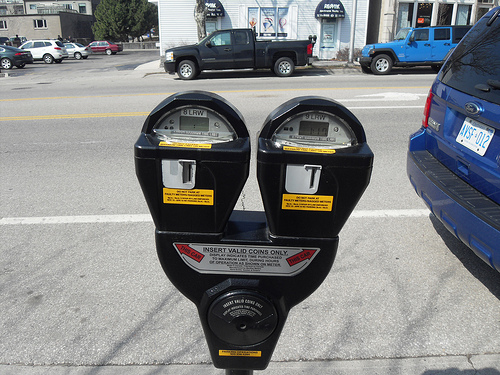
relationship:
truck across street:
[161, 26, 314, 77] [4, 77, 493, 359]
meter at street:
[131, 88, 378, 374] [4, 77, 493, 359]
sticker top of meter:
[160, 139, 213, 151] [131, 88, 378, 374]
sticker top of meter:
[283, 144, 337, 156] [131, 88, 378, 374]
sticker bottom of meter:
[161, 188, 215, 207] [131, 88, 378, 374]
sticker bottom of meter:
[279, 193, 335, 213] [131, 88, 378, 374]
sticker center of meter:
[174, 238, 320, 278] [131, 88, 378, 374]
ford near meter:
[403, 2, 495, 279] [131, 88, 378, 374]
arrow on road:
[337, 88, 429, 104] [4, 77, 493, 359]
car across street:
[360, 25, 469, 74] [4, 77, 493, 359]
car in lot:
[0, 46, 32, 72] [1, 41, 162, 76]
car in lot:
[88, 38, 121, 56] [1, 41, 162, 76]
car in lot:
[18, 38, 70, 65] [1, 41, 162, 76]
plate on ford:
[458, 117, 495, 156] [403, 2, 495, 279]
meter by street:
[131, 88, 378, 374] [4, 77, 493, 359]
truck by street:
[161, 26, 314, 77] [4, 77, 493, 359]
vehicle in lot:
[0, 46, 32, 72] [1, 41, 162, 76]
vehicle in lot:
[18, 38, 70, 65] [1, 41, 162, 76]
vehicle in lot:
[62, 41, 89, 62] [1, 41, 162, 76]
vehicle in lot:
[88, 38, 121, 56] [1, 41, 162, 76]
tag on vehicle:
[458, 117, 495, 156] [403, 2, 495, 279]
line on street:
[1, 109, 152, 123] [4, 77, 493, 359]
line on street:
[2, 206, 430, 228] [4, 77, 493, 359]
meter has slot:
[131, 88, 378, 374] [178, 159, 194, 186]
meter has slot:
[131, 88, 378, 374] [306, 166, 318, 191]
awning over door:
[201, 0, 226, 19] [203, 18, 223, 45]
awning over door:
[315, 0, 345, 22] [318, 20, 339, 59]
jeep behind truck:
[360, 25, 469, 74] [161, 26, 314, 77]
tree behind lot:
[93, 0, 159, 43] [1, 41, 162, 76]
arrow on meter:
[174, 240, 205, 266] [131, 88, 378, 374]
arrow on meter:
[286, 246, 316, 267] [131, 88, 378, 374]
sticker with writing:
[161, 188, 215, 207] [164, 193, 213, 200]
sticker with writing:
[279, 193, 335, 213] [284, 198, 332, 206]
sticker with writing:
[279, 193, 335, 213] [164, 193, 213, 200]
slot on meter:
[178, 159, 194, 186] [131, 88, 378, 374]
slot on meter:
[306, 166, 318, 191] [131, 88, 378, 374]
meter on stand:
[134, 88, 252, 238] [154, 235, 341, 371]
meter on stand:
[255, 93, 376, 238] [154, 235, 341, 371]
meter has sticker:
[134, 88, 252, 238] [161, 188, 215, 207]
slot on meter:
[178, 159, 194, 186] [134, 88, 252, 238]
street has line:
[4, 77, 493, 359] [1, 109, 152, 123]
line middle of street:
[1, 109, 152, 123] [4, 77, 493, 359]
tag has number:
[458, 117, 495, 156] [483, 133, 491, 150]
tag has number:
[458, 117, 495, 156] [475, 130, 481, 145]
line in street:
[2, 206, 430, 228] [4, 77, 493, 359]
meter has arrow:
[131, 88, 378, 374] [174, 240, 205, 266]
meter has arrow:
[131, 88, 378, 374] [286, 246, 316, 267]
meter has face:
[134, 88, 252, 238] [154, 109, 234, 138]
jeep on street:
[360, 25, 469, 74] [4, 77, 493, 359]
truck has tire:
[161, 26, 314, 77] [177, 58, 197, 81]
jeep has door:
[360, 25, 469, 74] [405, 39, 433, 63]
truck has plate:
[403, 2, 495, 279] [458, 117, 495, 156]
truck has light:
[161, 26, 314, 77] [305, 42, 312, 55]